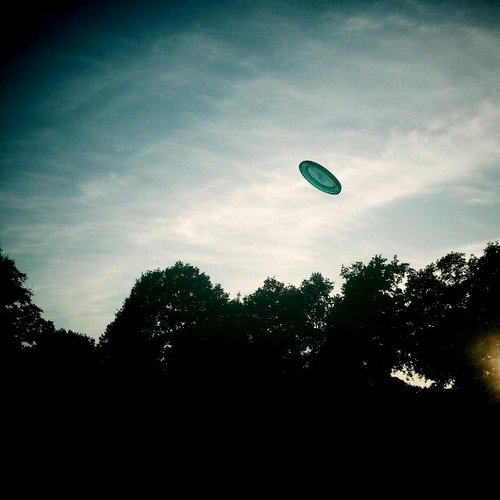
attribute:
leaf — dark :
[403, 262, 442, 313]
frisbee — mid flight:
[289, 158, 349, 199]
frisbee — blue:
[293, 147, 350, 206]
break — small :
[391, 367, 435, 389]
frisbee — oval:
[300, 152, 347, 198]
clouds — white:
[95, 100, 220, 205]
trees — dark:
[143, 255, 447, 339]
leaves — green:
[254, 283, 295, 309]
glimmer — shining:
[467, 327, 499, 379]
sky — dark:
[2, 3, 496, 344]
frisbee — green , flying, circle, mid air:
[299, 159, 341, 196]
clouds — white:
[369, 99, 442, 204]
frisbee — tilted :
[288, 149, 349, 213]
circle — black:
[297, 156, 343, 196]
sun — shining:
[469, 330, 498, 397]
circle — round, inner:
[306, 163, 340, 189]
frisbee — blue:
[292, 157, 344, 197]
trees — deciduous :
[103, 240, 498, 400]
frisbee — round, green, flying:
[297, 156, 345, 198]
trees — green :
[280, 296, 397, 383]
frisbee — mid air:
[295, 152, 348, 202]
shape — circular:
[294, 156, 342, 195]